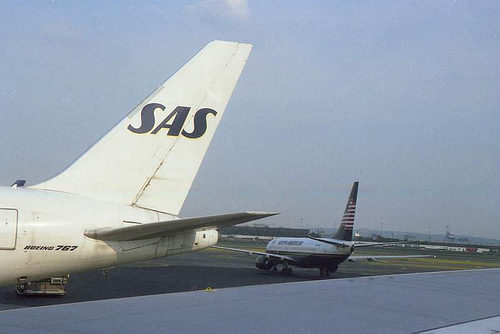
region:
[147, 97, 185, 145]
The letter A on the plane's tail.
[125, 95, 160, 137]
The letter S on the left on the tail of the plane.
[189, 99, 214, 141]
The letter S on the right on the tail of the plane.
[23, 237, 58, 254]
The word Boeing on the side of the plane.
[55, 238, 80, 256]
The number on the side of the plane.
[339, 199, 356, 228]
The American flag on the tail of the plane.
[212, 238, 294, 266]
The left wing on the plane with the American flag.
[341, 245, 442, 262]
The right wing on the plane with the American flag.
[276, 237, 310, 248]
The letters on the side of the plane with the American flag.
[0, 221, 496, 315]
The area the planes are parked.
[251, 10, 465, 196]
The sky is blue.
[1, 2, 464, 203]
The sky is clear.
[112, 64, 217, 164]
The wing says SAS.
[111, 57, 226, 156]
The text is black.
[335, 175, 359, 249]
American flag on the wing.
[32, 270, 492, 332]
The ground is grey.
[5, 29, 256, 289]
The airplane is white.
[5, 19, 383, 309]
Two airplanes are visible.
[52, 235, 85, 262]
Number 767 on plane.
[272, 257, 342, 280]
The wheels are black.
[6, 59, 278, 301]
tail of an airplane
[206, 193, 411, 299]
airplane with US flag painting on tail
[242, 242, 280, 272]
engine of airplane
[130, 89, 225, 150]
writing on airplane tail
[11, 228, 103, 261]
dark writing on white rear of plane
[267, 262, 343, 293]
landing gear of air plane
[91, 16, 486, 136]
blue and white skies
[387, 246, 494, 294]
green grass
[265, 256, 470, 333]
grey sidewalk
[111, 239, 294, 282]
dark grey tarmac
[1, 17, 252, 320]
the plane is white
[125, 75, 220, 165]
plane's tail says SAS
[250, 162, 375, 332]
plane has american flag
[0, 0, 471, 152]
the sky is blue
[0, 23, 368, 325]
planes are parked on runway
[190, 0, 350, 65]
a cloud is in the sky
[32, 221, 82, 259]
plane has number 767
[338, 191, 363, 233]
flag has red white and blue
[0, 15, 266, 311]
the plane is dirty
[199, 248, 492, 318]
the ground is gray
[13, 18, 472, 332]
A big clean airport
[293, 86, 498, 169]
a nice clear blue sky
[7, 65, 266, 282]
an airplane about to take off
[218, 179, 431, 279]
an airplane parked in position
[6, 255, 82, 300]
an airplane getting loaded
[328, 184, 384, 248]
an airplane with the united states sign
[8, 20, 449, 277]
to big airplanes in the background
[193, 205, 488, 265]
a massive airport yard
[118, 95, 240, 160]
airplane with an sas sign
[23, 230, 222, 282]
a boeing 767 airplane